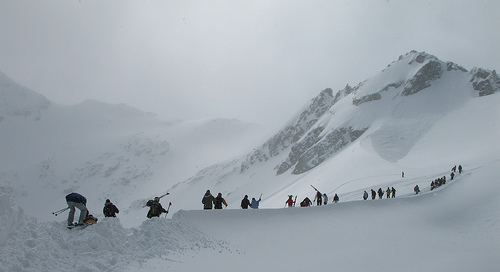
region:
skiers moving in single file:
[41, 147, 476, 234]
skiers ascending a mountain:
[52, 121, 479, 241]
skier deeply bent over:
[46, 186, 96, 232]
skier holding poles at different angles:
[126, 166, 176, 221]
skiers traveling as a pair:
[191, 177, 231, 217]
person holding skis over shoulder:
[306, 160, 328, 235]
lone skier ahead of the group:
[375, 150, 475, 195]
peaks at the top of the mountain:
[260, 35, 440, 180]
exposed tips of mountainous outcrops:
[230, 115, 370, 175]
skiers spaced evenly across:
[425, 162, 450, 197]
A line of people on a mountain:
[42, 158, 482, 219]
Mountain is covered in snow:
[283, 35, 485, 191]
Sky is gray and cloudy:
[48, 8, 440, 91]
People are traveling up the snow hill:
[56, 168, 473, 214]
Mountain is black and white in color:
[261, 33, 467, 180]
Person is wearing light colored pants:
[64, 196, 106, 227]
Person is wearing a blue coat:
[248, 190, 262, 214]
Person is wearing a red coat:
[281, 189, 295, 216]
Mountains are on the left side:
[6, 73, 156, 177]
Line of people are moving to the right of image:
[55, 156, 472, 228]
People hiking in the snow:
[46, 145, 479, 229]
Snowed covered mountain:
[292, 29, 497, 149]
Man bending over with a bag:
[41, 185, 100, 245]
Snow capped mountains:
[0, 54, 285, 186]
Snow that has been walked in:
[11, 228, 236, 268]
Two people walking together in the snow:
[235, 186, 265, 222]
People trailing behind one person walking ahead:
[396, 149, 485, 211]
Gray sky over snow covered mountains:
[45, 7, 316, 94]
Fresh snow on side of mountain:
[8, 106, 111, 159]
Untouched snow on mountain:
[265, 213, 492, 270]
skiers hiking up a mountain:
[308, 181, 323, 204]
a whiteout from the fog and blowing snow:
[0, 0, 313, 168]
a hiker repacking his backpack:
[52, 192, 97, 228]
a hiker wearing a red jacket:
[284, 193, 297, 205]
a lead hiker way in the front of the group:
[399, 170, 406, 178]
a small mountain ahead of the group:
[241, 49, 498, 180]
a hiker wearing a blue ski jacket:
[248, 191, 263, 208]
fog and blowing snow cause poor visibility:
[0, 1, 498, 193]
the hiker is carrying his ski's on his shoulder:
[142, 190, 171, 204]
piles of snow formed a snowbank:
[1, 175, 498, 270]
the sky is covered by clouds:
[112, 35, 164, 54]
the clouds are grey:
[116, 40, 195, 93]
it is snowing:
[13, 9, 475, 262]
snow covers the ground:
[155, 233, 262, 256]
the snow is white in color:
[155, 238, 212, 270]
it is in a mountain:
[5, 35, 428, 226]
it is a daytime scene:
[15, 11, 465, 252]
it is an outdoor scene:
[5, 10, 478, 265]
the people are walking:
[60, 140, 460, 225]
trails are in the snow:
[13, 231, 97, 253]